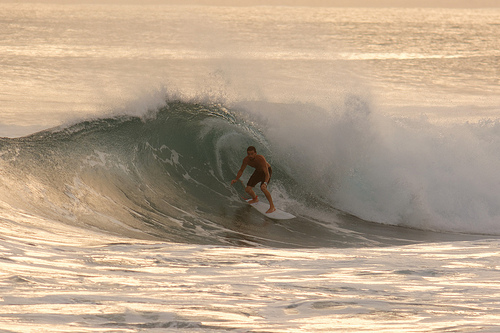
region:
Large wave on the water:
[32, 88, 203, 180]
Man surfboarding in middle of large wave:
[197, 87, 314, 252]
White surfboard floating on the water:
[227, 195, 299, 227]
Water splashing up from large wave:
[296, 81, 476, 208]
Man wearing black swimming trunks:
[235, 153, 285, 198]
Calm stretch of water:
[19, 11, 204, 73]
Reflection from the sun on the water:
[335, 44, 458, 68]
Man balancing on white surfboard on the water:
[227, 131, 296, 236]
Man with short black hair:
[238, 141, 264, 166]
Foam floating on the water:
[167, 211, 240, 244]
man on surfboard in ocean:
[224, 141, 303, 223]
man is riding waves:
[194, 99, 380, 256]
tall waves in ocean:
[55, 80, 415, 265]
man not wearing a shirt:
[223, 140, 278, 225]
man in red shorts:
[230, 133, 281, 224]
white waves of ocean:
[73, 78, 413, 218]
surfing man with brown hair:
[226, 136, 291, 226]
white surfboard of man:
[236, 173, 297, 223]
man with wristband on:
[225, 145, 307, 245]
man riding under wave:
[201, 122, 298, 222]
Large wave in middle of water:
[22, 74, 216, 217]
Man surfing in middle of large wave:
[192, 87, 337, 258]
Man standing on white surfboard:
[230, 132, 300, 231]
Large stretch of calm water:
[20, 11, 434, 71]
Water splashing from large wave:
[313, 114, 481, 188]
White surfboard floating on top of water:
[220, 206, 341, 255]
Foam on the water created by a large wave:
[62, 173, 127, 223]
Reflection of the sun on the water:
[347, 53, 444, 65]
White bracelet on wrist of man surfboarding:
[259, 178, 271, 194]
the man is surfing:
[213, 126, 321, 256]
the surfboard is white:
[241, 189, 313, 247]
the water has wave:
[81, 61, 378, 266]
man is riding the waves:
[208, 124, 292, 239]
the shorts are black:
[232, 169, 302, 191]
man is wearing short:
[238, 170, 279, 189]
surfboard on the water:
[235, 185, 305, 230]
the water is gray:
[160, 126, 221, 222]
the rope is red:
[230, 182, 265, 210]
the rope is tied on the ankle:
[231, 183, 268, 213]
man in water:
[213, 135, 285, 212]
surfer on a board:
[222, 116, 309, 253]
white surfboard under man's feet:
[234, 188, 298, 235]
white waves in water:
[336, 106, 465, 216]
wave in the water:
[78, 91, 236, 221]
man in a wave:
[225, 132, 318, 226]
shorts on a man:
[236, 161, 281, 197]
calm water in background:
[72, 4, 251, 101]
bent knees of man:
[219, 173, 286, 208]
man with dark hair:
[221, 138, 280, 213]